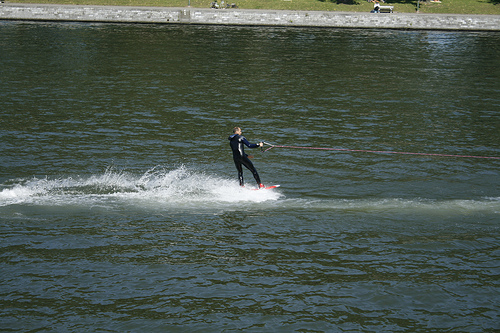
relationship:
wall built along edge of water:
[0, 5, 498, 29] [1, 17, 497, 331]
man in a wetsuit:
[228, 126, 267, 190] [228, 134, 264, 186]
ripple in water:
[0, 19, 500, 333] [1, 17, 497, 331]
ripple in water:
[0, 19, 500, 333] [312, 87, 477, 290]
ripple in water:
[1, 0, 497, 329] [1, 17, 497, 331]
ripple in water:
[0, 19, 500, 333] [95, 61, 495, 291]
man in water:
[228, 126, 267, 190] [274, 170, 382, 192]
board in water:
[242, 183, 281, 192] [274, 170, 382, 192]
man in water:
[228, 126, 267, 190] [1, 17, 497, 331]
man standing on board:
[228, 126, 267, 190] [242, 183, 281, 192]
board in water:
[242, 183, 281, 192] [1, 17, 497, 331]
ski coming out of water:
[206, 127, 296, 219] [1, 17, 497, 331]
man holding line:
[228, 123, 265, 190] [249, 134, 499, 174]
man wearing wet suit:
[228, 126, 267, 190] [227, 133, 262, 187]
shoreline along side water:
[5, 2, 499, 31] [1, 17, 497, 331]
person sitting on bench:
[372, 3, 381, 13] [364, 1, 418, 21]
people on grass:
[210, 0, 238, 10] [246, 0, 325, 10]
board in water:
[246, 181, 286, 195] [308, 155, 404, 278]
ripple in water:
[0, 19, 500, 333] [147, 228, 383, 305]